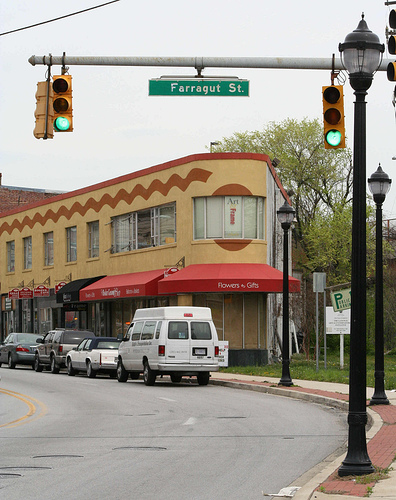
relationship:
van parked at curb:
[131, 304, 223, 386] [224, 351, 312, 408]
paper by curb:
[266, 483, 299, 496] [139, 365, 394, 497]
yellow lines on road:
[0, 385, 51, 433] [1, 362, 372, 497]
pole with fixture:
[333, 70, 372, 474] [368, 160, 393, 197]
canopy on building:
[57, 277, 87, 305] [2, 141, 315, 427]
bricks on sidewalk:
[327, 476, 362, 495] [316, 455, 370, 495]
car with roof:
[114, 303, 219, 385] [70, 331, 119, 350]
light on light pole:
[334, 49, 384, 78] [336, 7, 385, 473]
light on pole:
[48, 74, 73, 132] [26, 51, 394, 71]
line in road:
[10, 376, 46, 440] [3, 342, 366, 496]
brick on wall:
[378, 453, 389, 460] [217, 336, 274, 373]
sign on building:
[154, 246, 308, 307] [27, 120, 340, 399]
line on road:
[184, 414, 202, 427] [1, 362, 372, 497]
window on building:
[192, 196, 269, 235] [4, 185, 321, 396]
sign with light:
[146, 76, 252, 100] [48, 74, 79, 132]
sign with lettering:
[146, 76, 252, 100] [325, 307, 348, 327]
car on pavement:
[114, 303, 227, 391] [103, 387, 224, 452]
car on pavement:
[31, 327, 64, 365] [26, 353, 98, 418]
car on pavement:
[0, 332, 43, 368] [0, 361, 349, 499]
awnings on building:
[77, 268, 298, 301] [0, 140, 282, 335]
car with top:
[61, 335, 124, 379] [72, 335, 126, 348]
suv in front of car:
[29, 326, 95, 375] [61, 335, 124, 379]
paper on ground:
[262, 485, 299, 498] [225, 364, 395, 497]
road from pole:
[3, 342, 366, 496] [21, 45, 395, 72]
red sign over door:
[31, 284, 50, 299] [38, 302, 53, 336]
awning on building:
[49, 272, 103, 311] [4, 155, 295, 365]